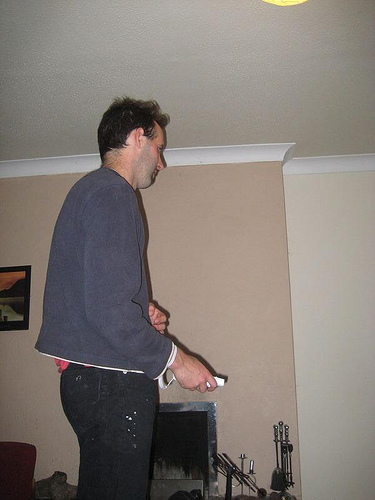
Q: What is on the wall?
A: Picture.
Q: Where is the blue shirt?
A: On man.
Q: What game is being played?
A: Wii.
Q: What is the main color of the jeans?
A: Black.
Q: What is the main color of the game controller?
A: White.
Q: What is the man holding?
A: Game controller.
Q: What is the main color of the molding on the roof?
A: White.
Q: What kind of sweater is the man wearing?
A: Long sleeve.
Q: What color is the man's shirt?
A: Gray.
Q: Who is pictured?
A: A man.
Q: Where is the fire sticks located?
A: Next to fireplace.